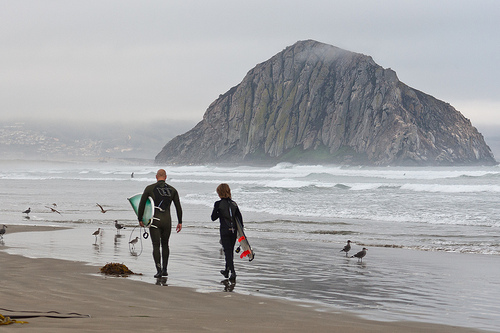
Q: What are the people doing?
A: Walking.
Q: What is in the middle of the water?
A: Mountain.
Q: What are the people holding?
A: Surfboards.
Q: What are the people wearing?
A: Wetsuits.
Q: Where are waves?
A: In the ocean.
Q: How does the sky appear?
A: Overcast.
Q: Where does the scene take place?
A: At the beach.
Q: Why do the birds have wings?
A: To fly.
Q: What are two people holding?
A: Surfboards.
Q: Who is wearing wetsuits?
A: Surfers.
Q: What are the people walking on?
A: Wet sand.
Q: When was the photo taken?
A: During the daytime.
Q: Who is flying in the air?
A: Two birds.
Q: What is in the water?
A: Birds.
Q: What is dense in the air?
A: Fog.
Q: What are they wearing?
A: Wetsuits.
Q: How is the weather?
A: Overcast.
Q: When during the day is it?
A: Early evening.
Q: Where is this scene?
A: Beachside.